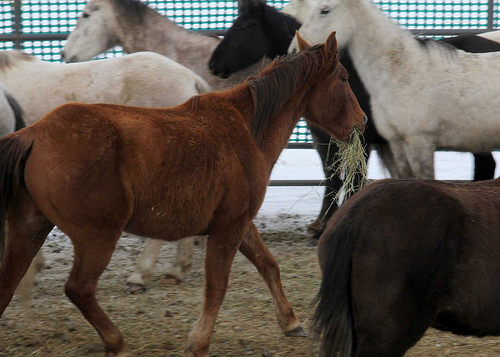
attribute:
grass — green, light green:
[284, 130, 370, 230]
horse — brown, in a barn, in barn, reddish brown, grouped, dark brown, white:
[0, 24, 369, 356]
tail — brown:
[1, 126, 35, 234]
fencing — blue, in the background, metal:
[0, 2, 498, 153]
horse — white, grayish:
[59, 2, 271, 96]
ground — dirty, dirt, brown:
[6, 144, 499, 355]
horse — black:
[209, 1, 499, 237]